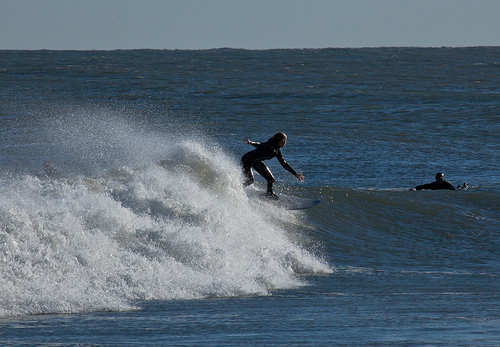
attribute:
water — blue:
[61, 64, 216, 176]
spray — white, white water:
[19, 106, 167, 180]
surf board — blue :
[251, 184, 324, 214]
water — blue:
[301, 261, 404, 325]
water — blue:
[0, 45, 499, 345]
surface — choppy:
[221, 303, 445, 330]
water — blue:
[65, 53, 401, 256]